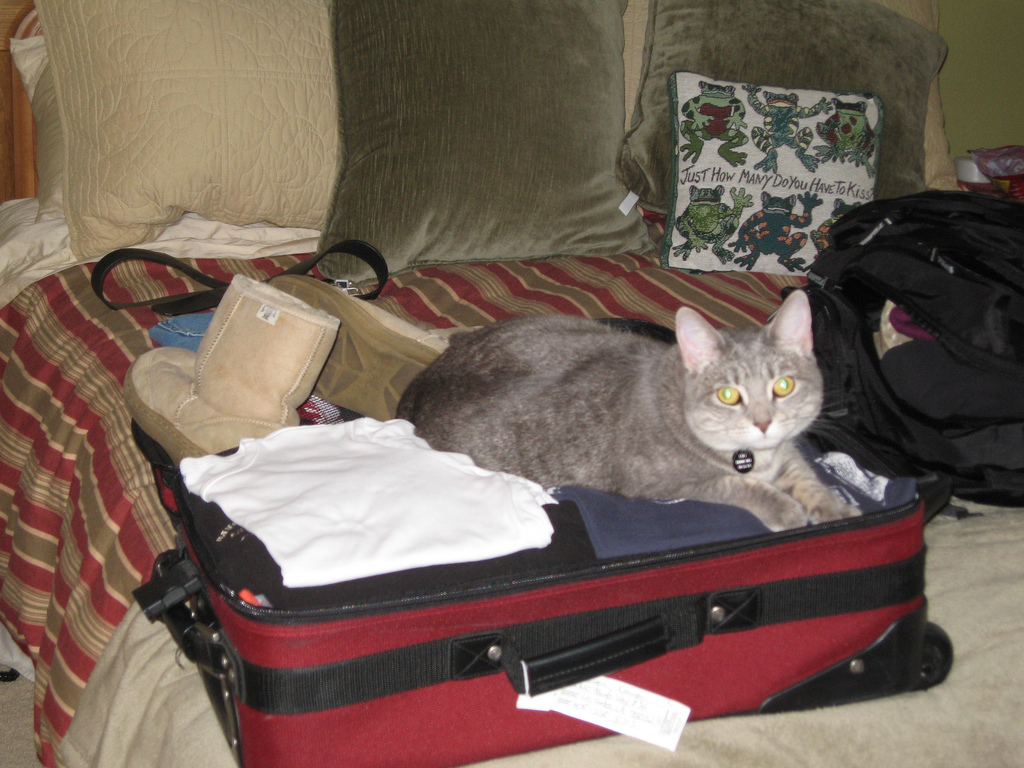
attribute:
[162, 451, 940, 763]
suitcase — red, black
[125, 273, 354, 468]
boots — short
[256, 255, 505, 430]
boots — short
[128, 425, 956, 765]
suitcase — red, open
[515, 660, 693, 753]
tag — paper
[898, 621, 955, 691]
wheel — black, plastic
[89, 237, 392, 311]
belt — folded, black, leather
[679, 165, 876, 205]
lettering — Just how many do you have to kiss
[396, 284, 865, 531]
cat — gray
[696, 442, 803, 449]
collar — not visible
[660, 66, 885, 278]
pillow — small, white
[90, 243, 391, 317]
belt — black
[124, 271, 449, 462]
boots — tan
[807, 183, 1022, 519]
duffel bag — black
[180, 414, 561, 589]
shirt — white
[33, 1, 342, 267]
pillow — light brown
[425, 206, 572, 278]
pillow — dark brown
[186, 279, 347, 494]
uggs — beige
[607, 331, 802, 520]
cat — grey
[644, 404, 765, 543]
cat — lying down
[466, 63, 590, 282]
pillow — green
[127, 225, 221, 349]
belt — black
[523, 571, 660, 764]
luggage tag — white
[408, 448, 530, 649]
white shirt — folded